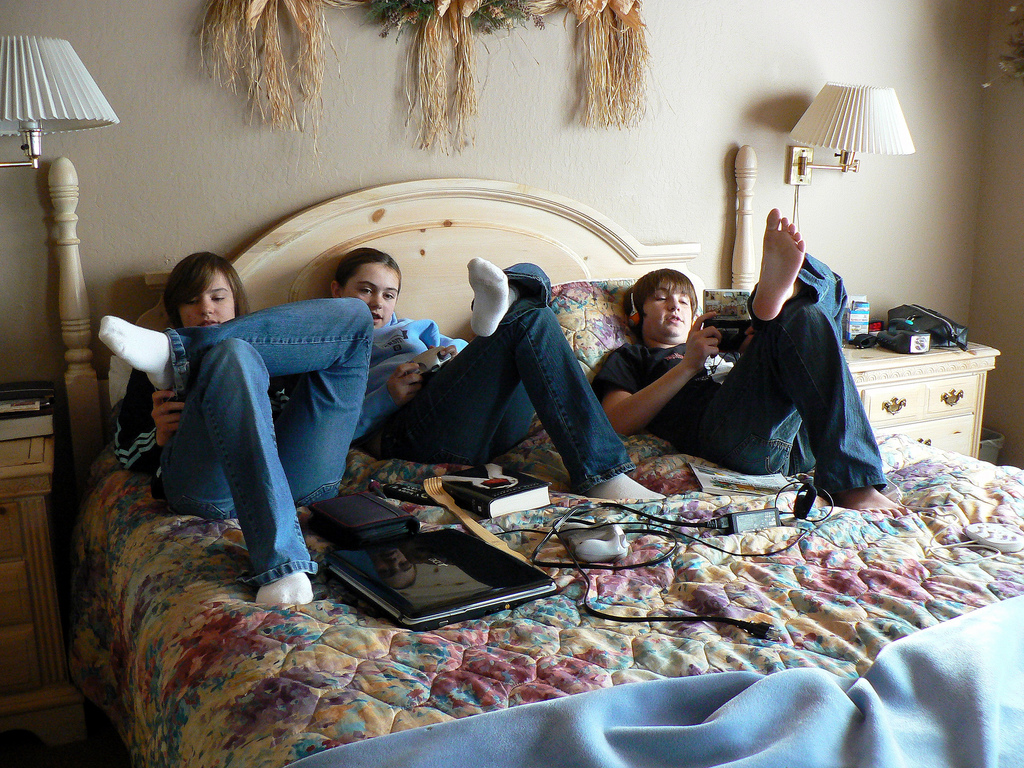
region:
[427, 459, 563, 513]
Black book with hands on it.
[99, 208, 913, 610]
Three kids laying in a bed.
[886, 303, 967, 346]
Black bag on end table.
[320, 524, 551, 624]
Black laptop on a bed.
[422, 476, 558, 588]
Brown wooden back scratcher on bed.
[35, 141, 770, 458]
Light beige wooden headboard to bed.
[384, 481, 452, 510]
Black remote control with grey buttons.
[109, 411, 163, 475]
Three light blue stripes on black sleeve.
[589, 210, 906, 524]
a young man with his foot propped on his knee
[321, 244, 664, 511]
a young woman wearing a white sock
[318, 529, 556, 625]
a closed shiny black laptop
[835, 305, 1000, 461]
a black landline phone on a small dresser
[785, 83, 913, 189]
a white lampshade hanging on a golden fixture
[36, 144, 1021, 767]
a two poster bed made of wood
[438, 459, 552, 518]
a black and white book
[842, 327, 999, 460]
a small wooden dresser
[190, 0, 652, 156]
hay hanging from a wreath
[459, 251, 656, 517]
THE GIRL IS WEARING WHITE SOCKS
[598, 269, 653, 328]
THE BOY IS WEARING EARPHONES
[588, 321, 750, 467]
THE BOY IS WEARING A BLACK SHIRT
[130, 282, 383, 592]
THE GIRL IS WEARING BLUE JEANS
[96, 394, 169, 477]
THE GIRL HAS WHITE STRIPES ON HER JACKET SLEEVE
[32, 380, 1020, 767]
THE BED SPREAD HAS A FLORAL PATTERN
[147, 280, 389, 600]
Girl wearing pants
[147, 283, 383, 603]
Girl is wearing pants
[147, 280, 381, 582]
Girl wearing jeans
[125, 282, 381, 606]
Girl is wearing jeans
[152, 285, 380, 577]
Girl wearing blue jeans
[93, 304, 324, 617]
Girl wearing white socks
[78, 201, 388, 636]
Girl is sitting on a bed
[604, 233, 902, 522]
boy laying on the bed with headphones on his ears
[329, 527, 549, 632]
laptop laying on the bed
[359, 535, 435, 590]
reflection of a boy on the laptop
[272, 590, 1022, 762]
blue blanket laying on the bottom of the bed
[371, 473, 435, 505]
remote on the bed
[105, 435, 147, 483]
blue stripes on the shirt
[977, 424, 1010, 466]
waste basket beside the dresser drawer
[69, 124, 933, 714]
people on the bed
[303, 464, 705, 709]
laptop on the bed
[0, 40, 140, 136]
lamp on the bed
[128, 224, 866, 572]
three children lounging on a bed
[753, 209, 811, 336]
young man's bare foot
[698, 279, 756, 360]
handheld game in young mans hand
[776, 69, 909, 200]
white sconce light on wall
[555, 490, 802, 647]
laptop charger laying on the bed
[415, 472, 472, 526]
wooden back scratcher between the girls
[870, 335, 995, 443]
wooden end table near the young man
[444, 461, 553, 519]
Twilight book laying on bed between girls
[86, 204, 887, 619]
three people lying on a bed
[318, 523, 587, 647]
closed laptop computer on a bed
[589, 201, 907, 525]
Young man listening with headphones on a bed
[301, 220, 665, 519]
Girl lying on a bed with legs crossed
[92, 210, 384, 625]
Boy wearing blue jeans on bed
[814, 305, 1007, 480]
white dresser beside a bed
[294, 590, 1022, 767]
blue blanket on a bed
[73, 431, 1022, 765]
multi-colored flowered bedspread on bed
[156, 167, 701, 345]
light brown wooden bed headboard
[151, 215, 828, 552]
Three people sitting in the bed.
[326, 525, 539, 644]
A black laptop laying on the bed.